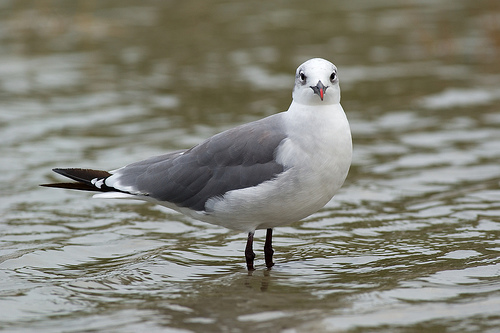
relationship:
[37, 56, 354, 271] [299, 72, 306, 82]
bird has eye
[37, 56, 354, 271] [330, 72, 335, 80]
bird has eye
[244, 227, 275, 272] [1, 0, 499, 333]
legs in water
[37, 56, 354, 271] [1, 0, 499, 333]
bird standing in water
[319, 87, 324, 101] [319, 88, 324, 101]
beak has orange strip